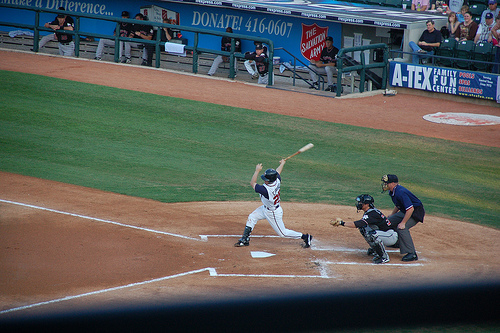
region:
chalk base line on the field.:
[84, 267, 180, 299]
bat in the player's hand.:
[285, 141, 318, 171]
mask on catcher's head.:
[354, 190, 374, 207]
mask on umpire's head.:
[375, 170, 402, 189]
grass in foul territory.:
[94, 124, 200, 151]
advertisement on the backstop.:
[398, 69, 450, 91]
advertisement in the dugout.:
[185, 14, 290, 24]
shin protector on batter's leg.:
[234, 226, 256, 241]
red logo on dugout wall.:
[297, 26, 323, 56]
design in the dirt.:
[420, 105, 494, 135]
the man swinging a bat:
[232, 130, 331, 267]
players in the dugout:
[36, 5, 401, 114]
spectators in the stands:
[415, 7, 492, 74]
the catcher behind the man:
[342, 190, 398, 270]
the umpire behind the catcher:
[377, 164, 439, 265]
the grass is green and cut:
[27, 87, 209, 193]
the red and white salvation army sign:
[296, 15, 331, 71]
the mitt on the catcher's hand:
[323, 213, 350, 229]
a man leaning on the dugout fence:
[40, 6, 78, 56]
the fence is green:
[11, 2, 273, 85]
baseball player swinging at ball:
[233, 135, 329, 254]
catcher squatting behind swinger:
[330, 192, 400, 264]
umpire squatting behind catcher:
[380, 160, 427, 265]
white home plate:
[247, 243, 276, 263]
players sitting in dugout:
[37, 13, 342, 80]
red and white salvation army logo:
[298, 19, 330, 66]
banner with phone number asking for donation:
[189, 5, 297, 41]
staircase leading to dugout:
[277, 44, 383, 104]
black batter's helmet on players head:
[259, 166, 276, 188]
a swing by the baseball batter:
[208, 133, 368, 281]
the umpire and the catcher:
[339, 171, 458, 275]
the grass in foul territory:
[33, 88, 174, 192]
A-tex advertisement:
[381, 56, 469, 108]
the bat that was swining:
[277, 135, 347, 162]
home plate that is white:
[246, 243, 284, 263]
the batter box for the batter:
[216, 231, 301, 253]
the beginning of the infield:
[11, 226, 136, 278]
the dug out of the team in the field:
[48, 5, 369, 117]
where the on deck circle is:
[419, 98, 484, 148]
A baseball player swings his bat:
[214, 127, 325, 250]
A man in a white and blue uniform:
[235, 152, 320, 254]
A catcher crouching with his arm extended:
[328, 174, 388, 271]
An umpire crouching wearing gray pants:
[374, 171, 437, 269]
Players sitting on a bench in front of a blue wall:
[194, 15, 286, 72]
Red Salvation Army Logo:
[296, 16, 328, 61]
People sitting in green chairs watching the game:
[405, 15, 496, 52]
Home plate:
[245, 240, 280, 266]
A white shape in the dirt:
[238, 239, 285, 268]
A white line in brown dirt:
[31, 196, 73, 251]